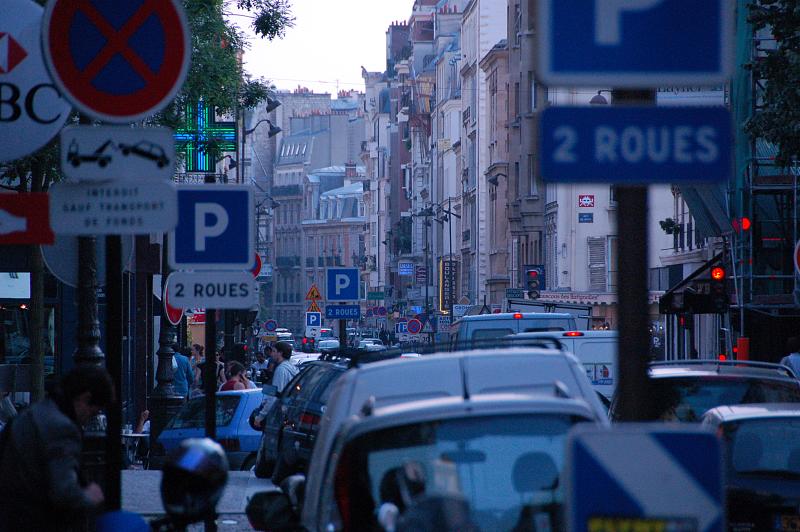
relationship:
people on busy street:
[145, 330, 302, 395] [0, 351, 800, 532]